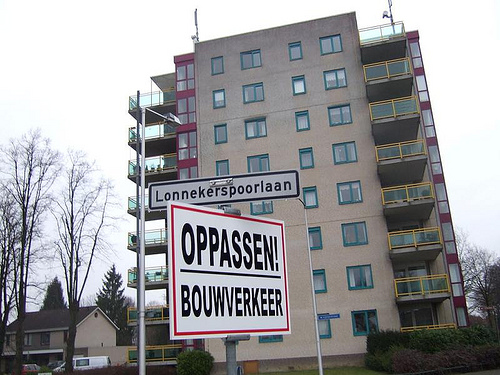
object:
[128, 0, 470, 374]
building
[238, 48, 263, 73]
window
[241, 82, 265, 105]
window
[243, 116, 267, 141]
window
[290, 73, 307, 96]
window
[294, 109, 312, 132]
window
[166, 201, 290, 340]
sign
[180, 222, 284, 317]
letters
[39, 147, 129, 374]
tree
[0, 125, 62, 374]
tree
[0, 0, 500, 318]
sky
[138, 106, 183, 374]
light pole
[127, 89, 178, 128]
balcony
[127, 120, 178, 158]
balcony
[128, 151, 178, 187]
balcony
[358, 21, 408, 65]
balcony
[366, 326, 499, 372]
bush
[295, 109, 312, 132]
trim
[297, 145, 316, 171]
trim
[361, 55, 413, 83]
trim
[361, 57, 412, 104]
balcony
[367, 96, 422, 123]
trim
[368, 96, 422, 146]
balcony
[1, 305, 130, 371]
house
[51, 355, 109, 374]
van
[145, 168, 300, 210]
sign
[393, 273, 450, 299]
guard rail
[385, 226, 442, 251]
guard rail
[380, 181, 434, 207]
guard rail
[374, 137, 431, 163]
guard rail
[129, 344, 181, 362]
guard rail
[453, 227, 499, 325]
tree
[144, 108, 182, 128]
street light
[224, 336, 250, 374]
post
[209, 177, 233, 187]
bracket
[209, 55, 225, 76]
window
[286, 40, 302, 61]
window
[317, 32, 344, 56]
window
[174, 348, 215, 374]
bush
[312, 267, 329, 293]
window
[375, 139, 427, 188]
balcony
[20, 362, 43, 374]
car